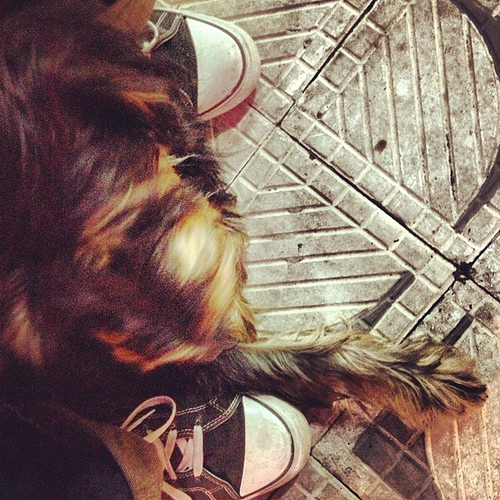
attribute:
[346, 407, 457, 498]
black tiles — black arc 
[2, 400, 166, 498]
jeans — blue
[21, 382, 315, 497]
shoe — white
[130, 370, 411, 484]
sneaker — white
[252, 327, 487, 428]
paw — brown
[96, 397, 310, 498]
shoe — black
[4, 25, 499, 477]
dog — shaggy 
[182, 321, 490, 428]
leg — exended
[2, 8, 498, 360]
coat — multi colored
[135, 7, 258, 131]
sneaker — white, black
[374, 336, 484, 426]
paw — dog's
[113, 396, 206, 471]
shoe lace — white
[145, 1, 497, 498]
floor — gray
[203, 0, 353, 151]
toes — white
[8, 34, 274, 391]
dog — shaggy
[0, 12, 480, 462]
dog — brown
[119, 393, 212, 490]
laces — white 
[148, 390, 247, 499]
seams — white 